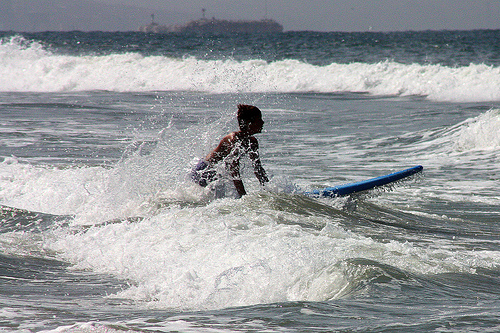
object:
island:
[132, 19, 284, 38]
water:
[0, 30, 498, 332]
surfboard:
[274, 164, 424, 212]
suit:
[190, 160, 222, 191]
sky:
[0, 1, 499, 33]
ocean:
[0, 29, 498, 332]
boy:
[187, 102, 271, 198]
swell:
[0, 30, 499, 104]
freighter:
[134, 0, 283, 35]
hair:
[235, 104, 264, 127]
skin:
[200, 114, 270, 199]